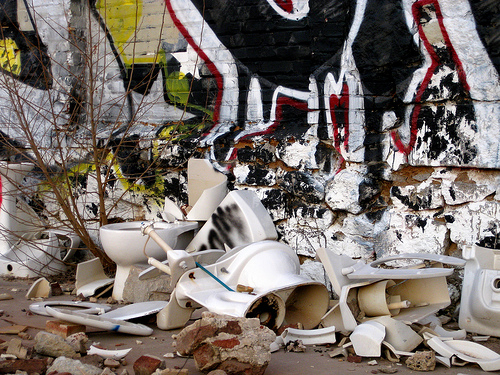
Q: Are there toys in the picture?
A: No, there are no toys.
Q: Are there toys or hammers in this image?
A: No, there are no toys or hammers.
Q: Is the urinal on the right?
A: Yes, the urinal is on the right of the image.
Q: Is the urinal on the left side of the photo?
A: No, the urinal is on the right of the image.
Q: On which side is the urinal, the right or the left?
A: The urinal is on the right of the image.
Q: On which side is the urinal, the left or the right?
A: The urinal is on the right of the image.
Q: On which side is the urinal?
A: The urinal is on the right of the image.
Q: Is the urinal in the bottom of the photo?
A: Yes, the urinal is in the bottom of the image.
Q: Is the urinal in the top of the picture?
A: No, the urinal is in the bottom of the image.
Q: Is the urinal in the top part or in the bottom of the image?
A: The urinal is in the bottom of the image.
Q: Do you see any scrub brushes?
A: No, there are no scrub brushes.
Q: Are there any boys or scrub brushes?
A: No, there are no scrub brushes or boys.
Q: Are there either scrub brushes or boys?
A: No, there are no scrub brushes or boys.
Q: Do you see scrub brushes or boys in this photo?
A: No, there are no scrub brushes or boys.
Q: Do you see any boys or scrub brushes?
A: No, there are no scrub brushes or boys.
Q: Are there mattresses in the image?
A: No, there are no mattresses.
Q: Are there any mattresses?
A: No, there are no mattresses.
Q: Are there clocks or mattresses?
A: No, there are no mattresses or clocks.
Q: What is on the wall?
A: The painting is on the wall.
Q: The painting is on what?
A: The painting is on the wall.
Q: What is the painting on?
A: The painting is on the wall.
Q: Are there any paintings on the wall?
A: Yes, there is a painting on the wall.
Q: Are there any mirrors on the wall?
A: No, there is a painting on the wall.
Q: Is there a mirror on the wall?
A: No, there is a painting on the wall.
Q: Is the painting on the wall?
A: Yes, the painting is on the wall.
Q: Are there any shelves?
A: No, there are no shelves.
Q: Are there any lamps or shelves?
A: No, there are no shelves or lamps.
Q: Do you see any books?
A: No, there are no books.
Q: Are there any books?
A: No, there are no books.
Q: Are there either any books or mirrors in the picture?
A: No, there are no books or mirrors.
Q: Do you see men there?
A: No, there are no men.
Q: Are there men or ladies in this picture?
A: No, there are no men or ladies.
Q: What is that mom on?
A: The mom is on the toilet.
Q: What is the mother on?
A: The mom is on the toilet.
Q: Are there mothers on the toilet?
A: Yes, there is a mother on the toilet.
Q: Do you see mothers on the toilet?
A: Yes, there is a mother on the toilet.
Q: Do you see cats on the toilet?
A: No, there is a mother on the toilet.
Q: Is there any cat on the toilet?
A: No, there is a mother on the toilet.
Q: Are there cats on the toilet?
A: No, there is a mother on the toilet.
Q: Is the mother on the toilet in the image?
A: Yes, the mother is on the toilet.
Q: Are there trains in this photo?
A: No, there are no trains.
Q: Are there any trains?
A: No, there are no trains.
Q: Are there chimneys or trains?
A: No, there are no trains or chimneys.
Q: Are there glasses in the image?
A: No, there are no glasses.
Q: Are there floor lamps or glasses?
A: No, there are no glasses or floor lamps.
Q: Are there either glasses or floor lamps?
A: No, there are no glasses or floor lamps.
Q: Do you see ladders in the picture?
A: No, there are no ladders.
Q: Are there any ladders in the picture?
A: No, there are no ladders.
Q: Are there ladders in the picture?
A: No, there are no ladders.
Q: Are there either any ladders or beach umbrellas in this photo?
A: No, there are no ladders or beach umbrellas.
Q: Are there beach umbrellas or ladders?
A: No, there are no ladders or beach umbrellas.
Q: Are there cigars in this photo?
A: No, there are no cigars.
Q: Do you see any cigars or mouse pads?
A: No, there are no cigars or mouse pads.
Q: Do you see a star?
A: Yes, there is a star.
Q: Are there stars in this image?
A: Yes, there is a star.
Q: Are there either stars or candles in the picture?
A: Yes, there is a star.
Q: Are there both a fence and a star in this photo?
A: No, there is a star but no fences.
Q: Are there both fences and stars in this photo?
A: No, there is a star but no fences.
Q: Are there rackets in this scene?
A: No, there are no rackets.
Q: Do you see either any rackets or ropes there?
A: No, there are no rackets or ropes.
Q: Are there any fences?
A: No, there are no fences.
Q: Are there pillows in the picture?
A: No, there are no pillows.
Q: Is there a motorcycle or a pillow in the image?
A: No, there are no pillows or motorcycles.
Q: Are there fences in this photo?
A: No, there are no fences.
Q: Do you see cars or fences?
A: No, there are no fences or cars.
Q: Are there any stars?
A: Yes, there is a star.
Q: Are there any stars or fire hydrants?
A: Yes, there is a star.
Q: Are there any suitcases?
A: No, there are no suitcases.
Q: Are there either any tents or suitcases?
A: No, there are no suitcases or tents.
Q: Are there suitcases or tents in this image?
A: No, there are no suitcases or tents.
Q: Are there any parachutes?
A: No, there are no parachutes.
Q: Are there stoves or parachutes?
A: No, there are no parachutes or stoves.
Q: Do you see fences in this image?
A: No, there are no fences.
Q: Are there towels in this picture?
A: No, there are no towels.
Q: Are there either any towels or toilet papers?
A: No, there are no towels or toilet papers.